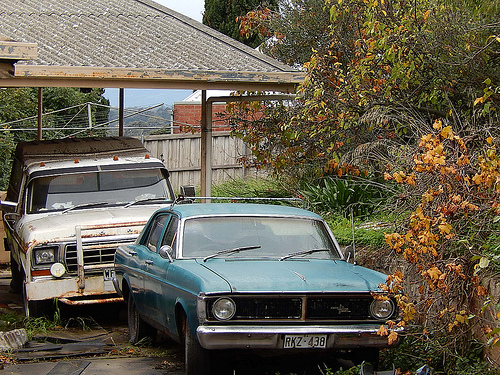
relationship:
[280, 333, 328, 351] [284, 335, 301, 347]
license plate with lettering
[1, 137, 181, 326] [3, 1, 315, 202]
vehicle under carport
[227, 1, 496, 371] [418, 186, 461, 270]
trees with leaves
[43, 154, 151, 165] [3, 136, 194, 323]
orange lights on truck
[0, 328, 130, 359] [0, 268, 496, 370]
debris on ground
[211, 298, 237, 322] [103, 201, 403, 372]
light of vehicle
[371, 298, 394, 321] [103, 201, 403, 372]
light of vehicle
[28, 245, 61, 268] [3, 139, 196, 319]
light of vehicle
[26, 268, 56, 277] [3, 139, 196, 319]
light of vehicle